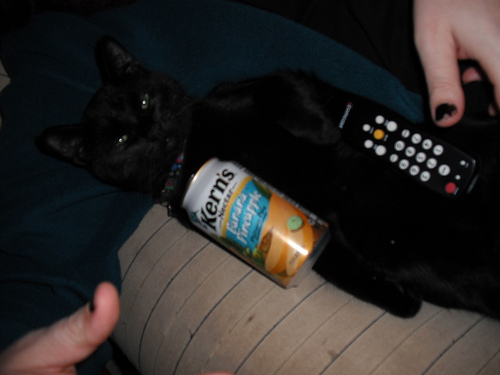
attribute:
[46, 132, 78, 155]
ear — cat's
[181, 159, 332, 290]
can — nectar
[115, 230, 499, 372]
fabric — beige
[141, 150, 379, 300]
can — aluminum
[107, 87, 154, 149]
eyes — dark 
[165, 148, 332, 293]
nector — pineapple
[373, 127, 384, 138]
button — yellow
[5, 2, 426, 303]
fabric — blue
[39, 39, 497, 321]
cat — black, laying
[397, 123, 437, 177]
buttons — white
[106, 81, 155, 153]
eyes — green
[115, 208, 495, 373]
stripes — blue